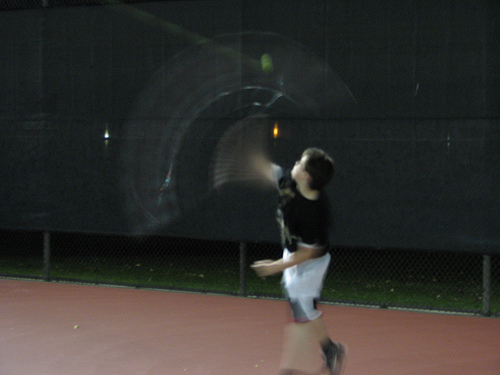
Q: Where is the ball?
A: The air.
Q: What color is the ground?
A: Red.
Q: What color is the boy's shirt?
A: Black.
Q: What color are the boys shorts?
A: White.